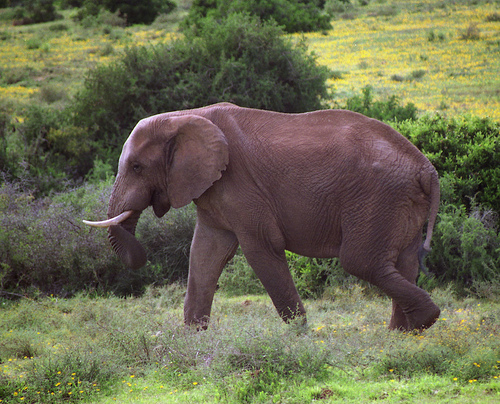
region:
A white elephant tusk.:
[82, 212, 133, 227]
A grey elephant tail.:
[423, 165, 442, 249]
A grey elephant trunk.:
[106, 199, 148, 268]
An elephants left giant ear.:
[161, 113, 228, 210]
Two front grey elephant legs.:
[185, 201, 310, 335]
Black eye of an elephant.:
[131, 162, 140, 169]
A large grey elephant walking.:
[83, 101, 440, 333]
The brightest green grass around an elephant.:
[102, 363, 497, 403]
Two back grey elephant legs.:
[338, 215, 440, 329]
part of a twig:
[368, 323, 401, 375]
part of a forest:
[256, 355, 266, 361]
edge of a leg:
[384, 258, 405, 280]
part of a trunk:
[119, 195, 131, 217]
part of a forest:
[461, 193, 473, 227]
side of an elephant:
[294, 191, 303, 194]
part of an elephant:
[287, 285, 301, 305]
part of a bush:
[314, 383, 321, 385]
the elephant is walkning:
[68, 92, 468, 344]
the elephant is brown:
[41, 36, 441, 368]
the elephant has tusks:
[66, 130, 178, 273]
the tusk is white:
[50, 173, 175, 251]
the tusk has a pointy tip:
[61, 200, 146, 246]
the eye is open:
[112, 146, 166, 178]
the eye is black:
[106, 152, 152, 194]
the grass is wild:
[114, 282, 366, 394]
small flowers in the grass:
[5, 351, 122, 398]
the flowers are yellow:
[3, 353, 120, 395]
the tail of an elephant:
[418, 168, 441, 268]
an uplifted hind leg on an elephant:
[340, 209, 449, 339]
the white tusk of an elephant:
[79, 207, 134, 227]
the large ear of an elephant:
[165, 114, 224, 208]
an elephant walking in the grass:
[76, 99, 454, 341]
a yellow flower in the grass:
[449, 374, 460, 383]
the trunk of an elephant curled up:
[105, 176, 149, 275]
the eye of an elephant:
[132, 161, 142, 171]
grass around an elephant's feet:
[3, 289, 497, 402]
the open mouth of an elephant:
[138, 189, 167, 223]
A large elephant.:
[83, 100, 441, 342]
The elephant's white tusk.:
[78, 213, 135, 230]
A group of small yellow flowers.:
[52, 370, 101, 400]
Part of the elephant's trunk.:
[110, 226, 144, 268]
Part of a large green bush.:
[193, 41, 288, 96]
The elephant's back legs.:
[341, 245, 443, 328]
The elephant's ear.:
[168, 112, 230, 214]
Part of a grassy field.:
[358, 34, 425, 56]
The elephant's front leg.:
[183, 221, 235, 328]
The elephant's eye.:
[127, 158, 143, 174]